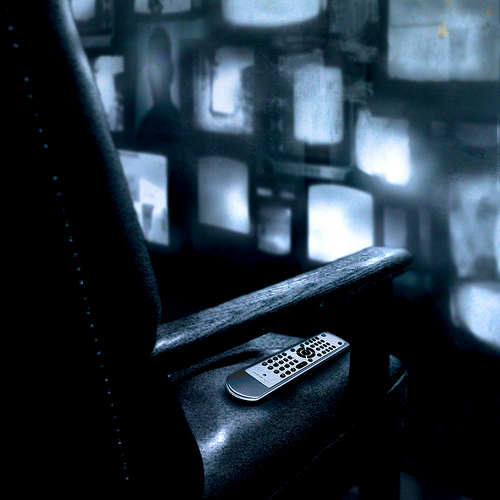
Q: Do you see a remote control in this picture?
A: Yes, there is a remote control.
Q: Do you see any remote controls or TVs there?
A: Yes, there is a remote control.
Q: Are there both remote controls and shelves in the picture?
A: No, there is a remote control but no shelves.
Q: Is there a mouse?
A: No, there are no computer mice.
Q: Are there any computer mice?
A: No, there are no computer mice.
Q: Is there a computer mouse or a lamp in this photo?
A: No, there are no computer mice or lamps.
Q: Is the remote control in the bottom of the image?
A: Yes, the remote control is in the bottom of the image.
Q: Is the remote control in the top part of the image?
A: No, the remote control is in the bottom of the image.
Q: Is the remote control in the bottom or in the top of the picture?
A: The remote control is in the bottom of the image.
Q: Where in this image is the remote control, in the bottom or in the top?
A: The remote control is in the bottom of the image.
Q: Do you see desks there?
A: No, there are no desks.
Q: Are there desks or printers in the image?
A: No, there are no desks or printers.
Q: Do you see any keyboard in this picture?
A: No, there are no keyboards.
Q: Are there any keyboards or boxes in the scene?
A: No, there are no keyboards or boxes.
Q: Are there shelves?
A: No, there are no shelves.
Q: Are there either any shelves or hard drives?
A: No, there are no shelves or hard drives.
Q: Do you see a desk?
A: No, there are no desks.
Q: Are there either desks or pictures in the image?
A: No, there are no desks or pictures.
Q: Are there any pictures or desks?
A: No, there are no desks or pictures.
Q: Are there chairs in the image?
A: Yes, there is a chair.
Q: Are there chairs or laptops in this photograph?
A: Yes, there is a chair.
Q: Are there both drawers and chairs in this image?
A: No, there is a chair but no drawers.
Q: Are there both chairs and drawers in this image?
A: No, there is a chair but no drawers.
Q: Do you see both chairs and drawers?
A: No, there is a chair but no drawers.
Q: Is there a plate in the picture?
A: No, there are no plates.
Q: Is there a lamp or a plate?
A: No, there are no plates or lamps.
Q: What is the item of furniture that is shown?
A: The piece of furniture is a chair.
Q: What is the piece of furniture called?
A: The piece of furniture is a chair.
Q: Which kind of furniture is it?
A: The piece of furniture is a chair.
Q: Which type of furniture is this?
A: This is a chair.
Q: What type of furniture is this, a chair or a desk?
A: This is a chair.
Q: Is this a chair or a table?
A: This is a chair.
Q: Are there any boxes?
A: No, there are no boxes.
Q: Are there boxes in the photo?
A: No, there are no boxes.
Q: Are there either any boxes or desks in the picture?
A: No, there are no boxes or desks.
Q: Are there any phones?
A: No, there are no phones.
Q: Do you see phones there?
A: No, there are no phones.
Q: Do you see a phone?
A: No, there are no phones.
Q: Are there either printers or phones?
A: No, there are no phones or printers.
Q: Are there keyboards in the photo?
A: No, there are no keyboards.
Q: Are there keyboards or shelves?
A: No, there are no keyboards or shelves.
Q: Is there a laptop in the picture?
A: No, there are no laptops.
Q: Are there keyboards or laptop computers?
A: No, there are no laptop computers or keyboards.